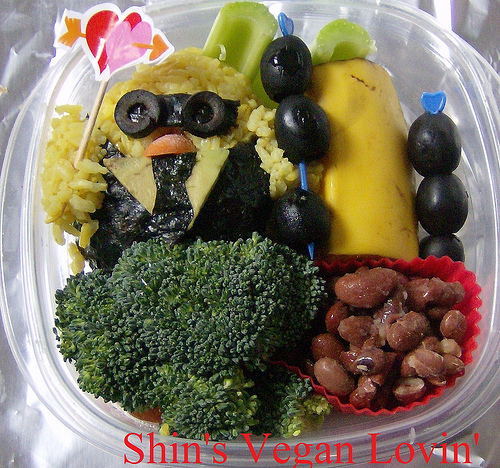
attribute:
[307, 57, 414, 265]
banana — half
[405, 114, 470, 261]
olives — black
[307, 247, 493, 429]
wrapper — red, silicone, cupcake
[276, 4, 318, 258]
toothpicks — blue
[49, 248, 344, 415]
broccoli — green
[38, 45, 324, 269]
rice — yellow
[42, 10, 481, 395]
food — suit, eyes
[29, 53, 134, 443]
container — plastic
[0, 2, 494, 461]
container — clear, plastic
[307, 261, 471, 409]
beans — brown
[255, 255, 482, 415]
cup — red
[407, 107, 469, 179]
olive — black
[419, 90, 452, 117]
heart — plastic, blue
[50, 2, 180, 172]
toothpick — valentines, heart, paper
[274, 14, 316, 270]
toothpick — blue, plastic, heart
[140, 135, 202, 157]
slice — small, carrot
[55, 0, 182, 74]
sticker — hearts, arrow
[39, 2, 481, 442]
food — made to look like a penguin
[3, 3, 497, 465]
plastic dish — clear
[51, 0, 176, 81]
sticker — heart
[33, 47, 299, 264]
rice — chicken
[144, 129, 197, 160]
carrot — small, piece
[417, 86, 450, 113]
heart — small, blue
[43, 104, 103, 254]
rice — yellow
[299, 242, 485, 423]
cup — silicone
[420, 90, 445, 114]
blue heart — small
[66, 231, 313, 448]
broccoli — bottom left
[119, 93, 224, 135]
sliced olives — black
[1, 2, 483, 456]
dish — plastic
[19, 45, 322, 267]
bird — rice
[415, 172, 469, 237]
olive — black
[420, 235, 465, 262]
olive — black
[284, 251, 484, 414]
cup — red, silicone, paper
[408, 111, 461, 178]
olive — black